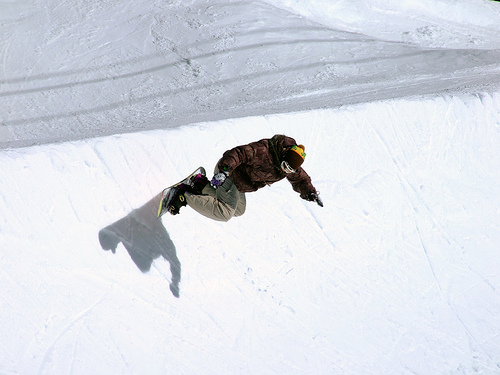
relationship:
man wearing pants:
[166, 134, 324, 222] [189, 176, 245, 221]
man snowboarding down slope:
[166, 134, 324, 222] [61, 118, 471, 355]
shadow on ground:
[98, 187, 184, 298] [1, 1, 498, 373]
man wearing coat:
[166, 134, 324, 222] [210, 134, 319, 202]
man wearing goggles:
[166, 134, 324, 222] [274, 156, 301, 181]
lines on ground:
[2, 24, 435, 127] [1, 1, 498, 373]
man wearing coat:
[174, 116, 315, 246] [219, 133, 285, 191]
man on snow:
[166, 134, 324, 222] [322, 222, 448, 373]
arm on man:
[284, 162, 316, 197] [166, 134, 324, 222]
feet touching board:
[164, 180, 187, 214] [154, 166, 208, 222]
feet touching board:
[184, 172, 209, 195] [154, 166, 208, 222]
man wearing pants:
[166, 134, 324, 222] [151, 161, 266, 251]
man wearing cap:
[166, 134, 324, 222] [284, 132, 309, 177]